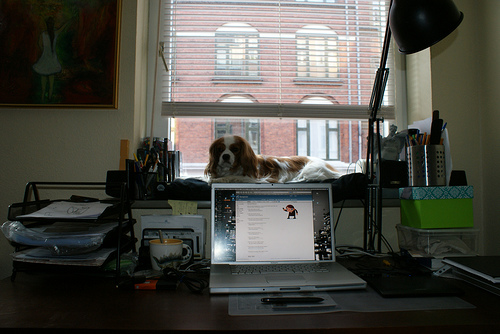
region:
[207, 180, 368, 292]
a laptop computer that is turned on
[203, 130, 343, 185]
a dog sitting in by the window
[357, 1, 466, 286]
a desk lamp that is turned off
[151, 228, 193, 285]
a coffee mug being used to hold pens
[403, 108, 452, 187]
a coffee mug that is being used to hold pens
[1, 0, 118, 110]
a picture on the all of a little girl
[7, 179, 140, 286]
a paper organizer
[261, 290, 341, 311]
a pen on top of pad of paper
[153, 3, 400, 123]
blinds for the window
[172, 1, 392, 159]
a building outside the window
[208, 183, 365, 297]
laptop screen is turned on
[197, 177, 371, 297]
the laptop is gray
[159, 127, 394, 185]
dog laying on window sill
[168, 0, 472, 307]
lamp shade near the laptop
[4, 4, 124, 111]
picture framed on wall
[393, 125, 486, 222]
pencil cup on a box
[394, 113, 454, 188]
pencil cup is silver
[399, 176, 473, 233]
box is green and blue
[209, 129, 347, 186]
dog is brown and white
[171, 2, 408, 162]
the building is red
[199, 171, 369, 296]
a laptop on a desk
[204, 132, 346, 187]
a dog on a window seal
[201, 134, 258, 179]
the head of a dog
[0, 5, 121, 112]
a photo in a frame hanging on a wall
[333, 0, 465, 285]
an extendable desk lamp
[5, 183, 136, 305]
paper organizer on a desk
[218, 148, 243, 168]
the nose of a dog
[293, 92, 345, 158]
a window in the building across the street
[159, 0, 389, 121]
a mini blind on a window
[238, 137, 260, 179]
the ear of a dog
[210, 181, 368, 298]
A laptop on the desk.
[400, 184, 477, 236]
A green box with a lid on it.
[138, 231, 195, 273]
A coffee mug on the desk.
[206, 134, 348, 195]
A King Charles Cavalier Spaniel in the window.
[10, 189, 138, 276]
Three filing trays on the desk.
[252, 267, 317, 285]
The mousepad on the laptop.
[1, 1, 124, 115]
A picture on the wall.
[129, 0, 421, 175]
A window with a dog in it.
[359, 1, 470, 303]
A desk lamp.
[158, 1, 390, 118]
Blinds on the window.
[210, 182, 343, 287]
A laptop computer that's on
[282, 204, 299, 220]
A character on the screen of the laptop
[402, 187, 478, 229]
A blue and green colored box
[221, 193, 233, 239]
Icons on a laptop's desktop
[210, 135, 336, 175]
A dog near the window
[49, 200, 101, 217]
A few sheets of paper in a bin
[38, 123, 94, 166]
White walls in the room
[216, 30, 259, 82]
A window of a nearby building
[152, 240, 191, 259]
A coffee cup on the desk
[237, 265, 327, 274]
Keyboard on a laptop